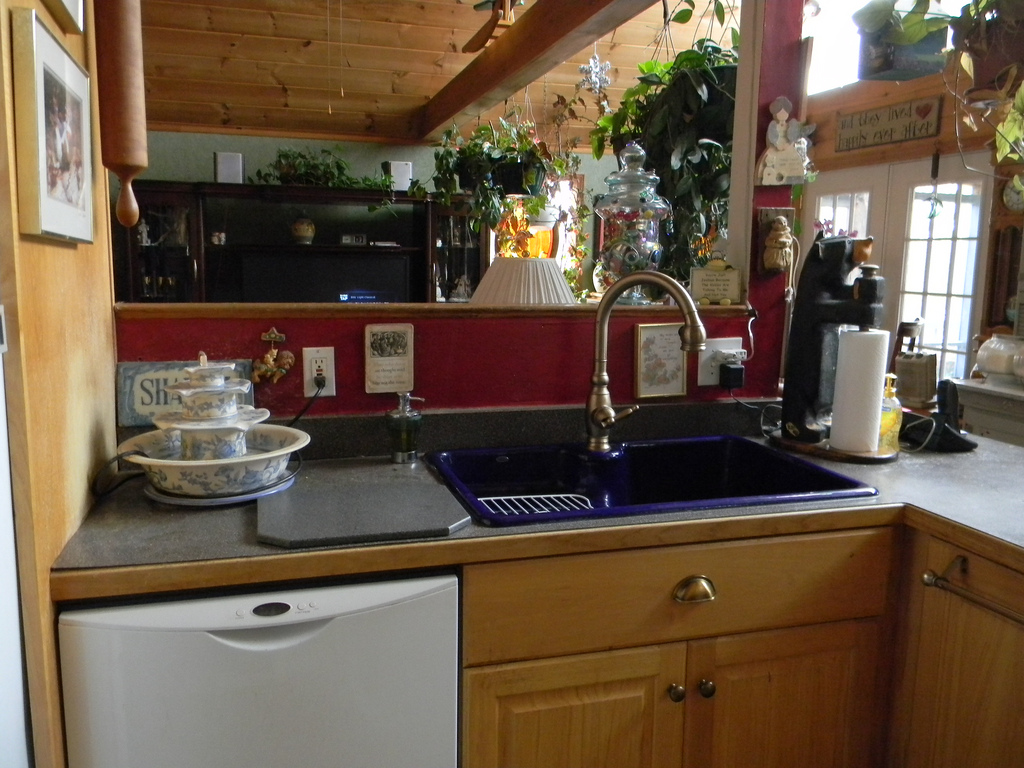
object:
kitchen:
[6, 0, 1024, 768]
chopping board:
[257, 453, 472, 549]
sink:
[425, 434, 880, 527]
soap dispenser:
[384, 392, 425, 464]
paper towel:
[829, 328, 890, 451]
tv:
[243, 245, 410, 303]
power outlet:
[696, 337, 746, 387]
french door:
[778, 163, 888, 378]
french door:
[881, 148, 994, 380]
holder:
[829, 263, 890, 451]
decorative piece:
[755, 96, 817, 186]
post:
[726, 0, 802, 310]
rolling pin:
[95, 0, 150, 228]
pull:
[671, 574, 717, 604]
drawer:
[463, 503, 904, 768]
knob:
[666, 684, 685, 703]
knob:
[696, 681, 716, 700]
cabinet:
[684, 616, 887, 768]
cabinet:
[463, 642, 688, 768]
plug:
[314, 373, 327, 390]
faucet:
[584, 271, 707, 455]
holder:
[767, 230, 902, 466]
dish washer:
[57, 574, 459, 768]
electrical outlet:
[302, 347, 337, 398]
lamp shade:
[468, 257, 578, 303]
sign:
[833, 96, 939, 153]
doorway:
[798, 149, 994, 381]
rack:
[477, 494, 594, 516]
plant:
[408, 105, 566, 234]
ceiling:
[94, 0, 739, 155]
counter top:
[50, 398, 1024, 574]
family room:
[88, 70, 813, 299]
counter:
[47, 427, 1022, 767]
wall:
[113, 307, 778, 428]